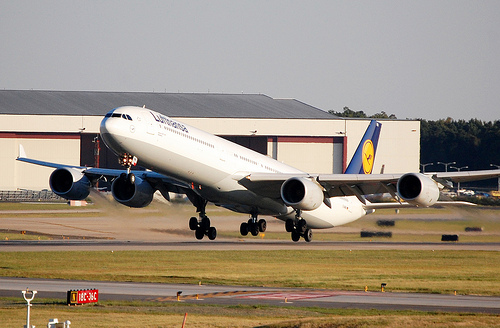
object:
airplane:
[15, 105, 498, 242]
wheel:
[201, 220, 209, 228]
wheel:
[188, 217, 196, 230]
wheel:
[209, 227, 217, 239]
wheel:
[195, 230, 204, 239]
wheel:
[298, 220, 307, 231]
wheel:
[285, 220, 293, 232]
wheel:
[305, 228, 312, 241]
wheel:
[291, 232, 301, 242]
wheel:
[250, 224, 258, 235]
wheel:
[240, 223, 247, 236]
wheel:
[247, 219, 252, 224]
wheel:
[258, 219, 266, 231]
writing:
[149, 111, 190, 134]